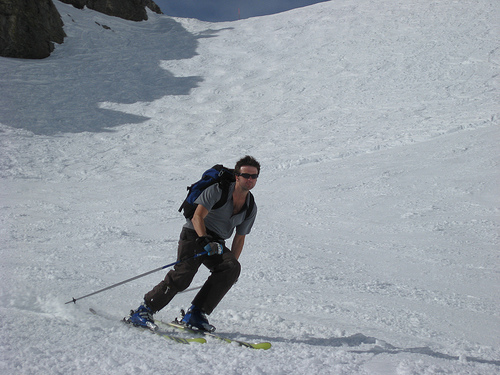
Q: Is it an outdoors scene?
A: Yes, it is outdoors.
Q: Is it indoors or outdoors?
A: It is outdoors.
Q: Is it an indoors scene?
A: No, it is outdoors.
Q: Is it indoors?
A: No, it is outdoors.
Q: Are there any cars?
A: No, there are no cars.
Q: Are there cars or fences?
A: No, there are no cars or fences.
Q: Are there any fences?
A: No, there are no fences.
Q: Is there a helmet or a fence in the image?
A: No, there are no fences or helmets.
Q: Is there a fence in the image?
A: No, there are no fences.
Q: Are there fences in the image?
A: No, there are no fences.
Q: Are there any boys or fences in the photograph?
A: No, there are no fences or boys.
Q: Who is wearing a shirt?
A: The man is wearing a shirt.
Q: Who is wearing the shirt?
A: The man is wearing a shirt.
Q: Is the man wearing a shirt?
A: Yes, the man is wearing a shirt.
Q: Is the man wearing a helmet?
A: No, the man is wearing a shirt.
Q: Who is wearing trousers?
A: The man is wearing trousers.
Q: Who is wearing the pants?
A: The man is wearing trousers.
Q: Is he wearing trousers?
A: Yes, the man is wearing trousers.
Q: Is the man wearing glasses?
A: No, the man is wearing trousers.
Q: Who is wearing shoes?
A: The man is wearing shoes.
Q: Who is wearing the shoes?
A: The man is wearing shoes.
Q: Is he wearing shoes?
A: Yes, the man is wearing shoes.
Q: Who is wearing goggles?
A: The man is wearing goggles.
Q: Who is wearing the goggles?
A: The man is wearing goggles.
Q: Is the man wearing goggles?
A: Yes, the man is wearing goggles.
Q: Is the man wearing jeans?
A: No, the man is wearing goggles.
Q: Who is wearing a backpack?
A: The man is wearing a backpack.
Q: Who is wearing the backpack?
A: The man is wearing a backpack.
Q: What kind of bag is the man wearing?
A: The man is wearing a backpack.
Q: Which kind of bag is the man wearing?
A: The man is wearing a backpack.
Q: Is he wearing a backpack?
A: Yes, the man is wearing a backpack.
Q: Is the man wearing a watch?
A: No, the man is wearing a backpack.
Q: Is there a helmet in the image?
A: No, there are no helmets.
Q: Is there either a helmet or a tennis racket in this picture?
A: No, there are no helmets or rackets.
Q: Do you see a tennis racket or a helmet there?
A: No, there are no helmets or rackets.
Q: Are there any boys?
A: No, there are no boys.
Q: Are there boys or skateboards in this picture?
A: No, there are no boys or skateboards.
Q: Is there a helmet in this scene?
A: No, there are no helmets.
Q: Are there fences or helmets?
A: No, there are no helmets or fences.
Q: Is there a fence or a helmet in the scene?
A: No, there are no helmets or fences.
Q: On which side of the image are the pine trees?
A: The pine trees are on the left of the image.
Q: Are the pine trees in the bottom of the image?
A: No, the pine trees are in the top of the image.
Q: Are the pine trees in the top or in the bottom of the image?
A: The pine trees are in the top of the image.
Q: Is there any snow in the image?
A: Yes, there is snow.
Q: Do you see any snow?
A: Yes, there is snow.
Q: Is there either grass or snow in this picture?
A: Yes, there is snow.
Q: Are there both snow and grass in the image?
A: No, there is snow but no grass.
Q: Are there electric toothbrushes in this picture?
A: No, there are no electric toothbrushes.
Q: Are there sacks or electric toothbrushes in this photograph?
A: No, there are no electric toothbrushes or sacks.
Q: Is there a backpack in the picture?
A: Yes, there is a backpack.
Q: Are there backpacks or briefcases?
A: Yes, there is a backpack.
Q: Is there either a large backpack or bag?
A: Yes, there is a large backpack.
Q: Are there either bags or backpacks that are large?
A: Yes, the backpack is large.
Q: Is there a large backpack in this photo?
A: Yes, there is a large backpack.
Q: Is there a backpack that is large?
A: Yes, there is a backpack that is large.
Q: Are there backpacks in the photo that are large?
A: Yes, there is a backpack that is large.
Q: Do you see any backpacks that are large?
A: Yes, there is a backpack that is large.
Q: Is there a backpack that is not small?
A: Yes, there is a large backpack.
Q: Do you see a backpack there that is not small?
A: Yes, there is a large backpack.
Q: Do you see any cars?
A: No, there are no cars.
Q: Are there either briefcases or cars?
A: No, there are no cars or briefcases.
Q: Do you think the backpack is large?
A: Yes, the backpack is large.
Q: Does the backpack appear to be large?
A: Yes, the backpack is large.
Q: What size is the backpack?
A: The backpack is large.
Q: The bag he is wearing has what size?
A: The backpack is large.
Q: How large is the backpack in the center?
A: The backpack is large.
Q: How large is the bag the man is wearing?
A: The backpack is large.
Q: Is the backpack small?
A: No, the backpack is large.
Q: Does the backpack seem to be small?
A: No, the backpack is large.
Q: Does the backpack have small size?
A: No, the backpack is large.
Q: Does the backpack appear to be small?
A: No, the backpack is large.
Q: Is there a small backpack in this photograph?
A: No, there is a backpack but it is large.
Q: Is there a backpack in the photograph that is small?
A: No, there is a backpack but it is large.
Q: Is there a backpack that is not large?
A: No, there is a backpack but it is large.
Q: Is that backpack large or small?
A: The backpack is large.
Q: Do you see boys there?
A: No, there are no boys.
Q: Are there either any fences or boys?
A: No, there are no boys or fences.